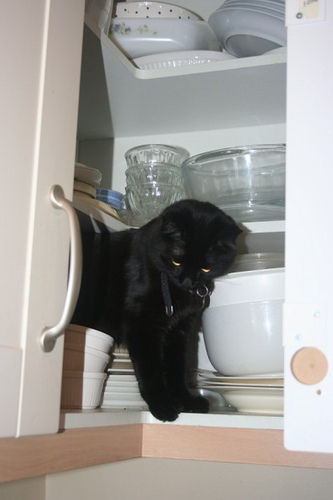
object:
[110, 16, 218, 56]
baking pan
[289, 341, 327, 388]
hinge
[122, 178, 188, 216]
bowl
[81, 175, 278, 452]
cat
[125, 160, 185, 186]
bowl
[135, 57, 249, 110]
ground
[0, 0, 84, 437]
door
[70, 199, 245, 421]
black cat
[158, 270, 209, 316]
collar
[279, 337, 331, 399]
circle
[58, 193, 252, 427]
cat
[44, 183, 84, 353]
cabinet handle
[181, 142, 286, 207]
bowl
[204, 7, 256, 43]
bowls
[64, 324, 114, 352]
bowl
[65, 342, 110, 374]
bowl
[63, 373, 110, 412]
bowl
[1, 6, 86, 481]
cupboard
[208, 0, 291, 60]
dishes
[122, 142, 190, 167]
bowl